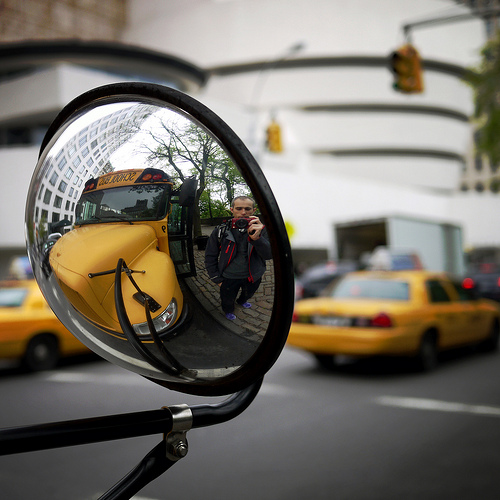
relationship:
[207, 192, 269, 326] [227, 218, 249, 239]
man holding camera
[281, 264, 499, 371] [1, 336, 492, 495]
taxi in street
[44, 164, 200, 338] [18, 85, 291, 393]
bus in mirror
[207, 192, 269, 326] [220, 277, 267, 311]
man wearing pants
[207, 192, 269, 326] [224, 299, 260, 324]
man wearing sneakers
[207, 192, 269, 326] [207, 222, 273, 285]
man wearing jacket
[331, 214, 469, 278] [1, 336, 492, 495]
truck on street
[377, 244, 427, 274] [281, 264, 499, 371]
ad on taxi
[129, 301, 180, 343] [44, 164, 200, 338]
headlights on bus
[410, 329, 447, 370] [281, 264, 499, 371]
back tire on taxi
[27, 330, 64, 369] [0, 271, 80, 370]
tire on cab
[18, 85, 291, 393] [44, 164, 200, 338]
mirror has bus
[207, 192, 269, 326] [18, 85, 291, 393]
man in mirror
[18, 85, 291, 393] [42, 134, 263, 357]
mirror has reflection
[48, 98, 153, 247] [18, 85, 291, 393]
building in mirror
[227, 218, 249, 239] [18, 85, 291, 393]
camera in mirror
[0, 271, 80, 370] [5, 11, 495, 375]
cab in background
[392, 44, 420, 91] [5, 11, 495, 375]
light in background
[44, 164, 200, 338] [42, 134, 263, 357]
bus in reflection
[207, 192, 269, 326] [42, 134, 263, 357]
man in reflection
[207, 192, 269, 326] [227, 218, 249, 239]
man with camera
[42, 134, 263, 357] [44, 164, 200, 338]
reflection of bus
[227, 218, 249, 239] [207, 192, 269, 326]
camera for photographing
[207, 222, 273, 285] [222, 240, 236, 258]
jacket has trim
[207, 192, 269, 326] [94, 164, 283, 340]
man takes photo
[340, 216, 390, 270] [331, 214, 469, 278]
door on truck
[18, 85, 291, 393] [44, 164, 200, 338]
mirror on bus